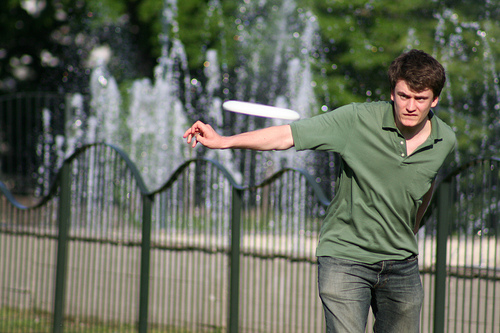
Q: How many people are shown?
A: One.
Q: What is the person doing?
A: Throwing frisbee.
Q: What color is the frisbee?
A: White.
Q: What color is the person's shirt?
A: Green.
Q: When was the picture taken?
A: Daytime.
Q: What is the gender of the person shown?
A: Male.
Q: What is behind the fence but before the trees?
A: Water fountains.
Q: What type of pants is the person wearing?
A: Jeans.